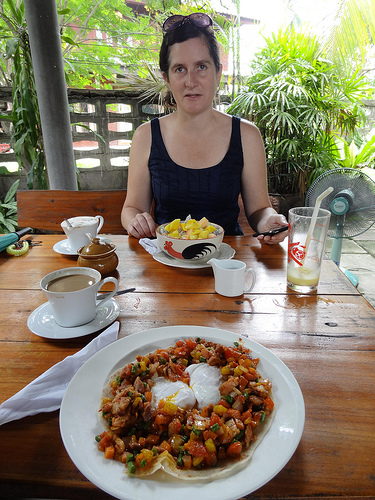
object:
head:
[157, 13, 224, 116]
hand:
[256, 212, 291, 246]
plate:
[138, 237, 235, 270]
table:
[0, 231, 375, 499]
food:
[163, 214, 221, 240]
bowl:
[153, 222, 224, 262]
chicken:
[161, 240, 220, 262]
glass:
[286, 204, 332, 299]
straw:
[315, 186, 333, 214]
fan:
[305, 166, 375, 240]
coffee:
[45, 274, 98, 292]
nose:
[182, 74, 198, 89]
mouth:
[181, 90, 204, 102]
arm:
[119, 120, 155, 231]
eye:
[190, 60, 209, 79]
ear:
[218, 64, 225, 83]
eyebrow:
[169, 62, 187, 69]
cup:
[38, 266, 119, 329]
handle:
[96, 274, 121, 310]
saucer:
[26, 293, 120, 341]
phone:
[251, 220, 298, 241]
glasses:
[159, 12, 212, 43]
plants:
[55, 0, 159, 90]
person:
[120, 13, 290, 244]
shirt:
[147, 114, 246, 237]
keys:
[5, 234, 44, 259]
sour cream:
[68, 218, 96, 235]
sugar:
[74, 238, 120, 275]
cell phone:
[251, 218, 306, 236]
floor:
[325, 220, 375, 309]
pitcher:
[60, 214, 105, 250]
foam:
[95, 213, 104, 234]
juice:
[287, 269, 319, 284]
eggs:
[171, 223, 187, 229]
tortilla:
[96, 337, 274, 477]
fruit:
[161, 219, 184, 240]